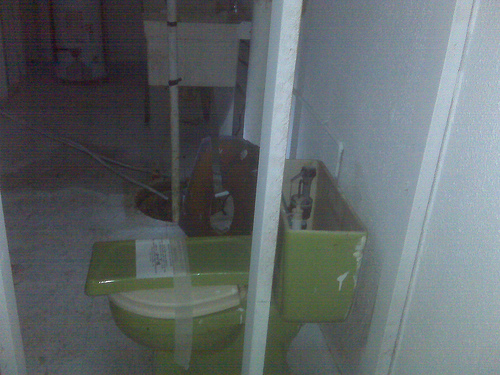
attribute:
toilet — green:
[90, 170, 366, 360]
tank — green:
[182, 125, 367, 327]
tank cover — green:
[274, 157, 363, 337]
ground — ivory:
[440, 126, 468, 155]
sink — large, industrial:
[132, 13, 252, 91]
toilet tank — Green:
[91, 222, 358, 352]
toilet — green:
[81, 150, 371, 354]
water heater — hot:
[50, 1, 105, 80]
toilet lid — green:
[83, 227, 277, 306]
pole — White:
[139, 48, 189, 228]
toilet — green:
[86, 153, 371, 373]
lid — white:
[114, 283, 243, 324]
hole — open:
[128, 163, 198, 234]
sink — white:
[128, 15, 263, 96]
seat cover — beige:
[106, 282, 248, 319]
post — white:
[213, 46, 337, 324]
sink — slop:
[140, 14, 253, 94]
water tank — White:
[41, 0, 112, 82]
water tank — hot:
[50, 1, 107, 82]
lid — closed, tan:
[111, 288, 239, 321]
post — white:
[159, 13, 193, 228]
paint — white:
[346, 237, 373, 293]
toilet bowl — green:
[110, 284, 254, 364]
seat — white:
[110, 284, 242, 315]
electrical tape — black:
[160, 4, 184, 104]